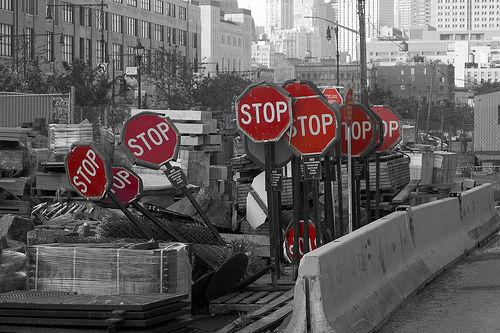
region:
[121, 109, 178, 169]
a red stop sign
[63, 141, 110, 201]
a red stop sign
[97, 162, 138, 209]
a red stop sign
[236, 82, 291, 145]
a red stop sign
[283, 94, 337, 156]
a red stop sign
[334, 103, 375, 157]
a red stop sign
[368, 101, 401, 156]
a red stop sign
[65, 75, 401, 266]
many stop signs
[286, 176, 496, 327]
the stone wall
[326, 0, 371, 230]
the long poles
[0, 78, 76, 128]
the fence on left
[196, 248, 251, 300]
the bottom of stop sign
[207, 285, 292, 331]
the palettes on ground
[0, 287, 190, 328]
the doors stacked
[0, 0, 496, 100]
buildings in background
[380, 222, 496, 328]
the pave sidewalk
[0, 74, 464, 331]
all under construction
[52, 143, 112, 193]
this is a stop sign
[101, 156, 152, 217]
this is a stop sign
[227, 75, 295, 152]
this is a stop sign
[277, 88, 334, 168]
this is a stop sign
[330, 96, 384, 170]
this is a stop sign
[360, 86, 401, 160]
this is a stop sign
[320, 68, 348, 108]
this is a stop sign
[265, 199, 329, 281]
this is a stop sign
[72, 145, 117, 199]
Red stop sign in a yard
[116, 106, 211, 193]
Red stop sign leaning over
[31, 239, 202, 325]
Pallet of gray items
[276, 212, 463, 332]
Cement barrier wall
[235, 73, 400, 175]
Group of stop signs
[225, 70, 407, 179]
Red and white stop signs together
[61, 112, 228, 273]
Three stop signs leaning over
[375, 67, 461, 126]
Gray building in a city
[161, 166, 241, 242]
Pole on a stop sign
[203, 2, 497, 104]
cluster of city buildings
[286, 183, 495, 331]
three sections of concrete barrier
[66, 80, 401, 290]
stop signs on stands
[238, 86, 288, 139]
red sign with white word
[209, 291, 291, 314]
boards on wood plank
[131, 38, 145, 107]
light on top of pole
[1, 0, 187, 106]
windows on side of building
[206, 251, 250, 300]
round base of sign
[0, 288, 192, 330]
stack of flat planks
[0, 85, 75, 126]
pole of chain link fence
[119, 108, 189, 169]
red and white oblong sign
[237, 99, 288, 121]
white words on the post